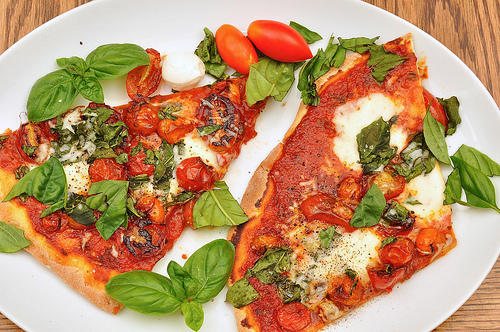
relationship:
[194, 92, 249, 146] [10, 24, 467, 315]
onion on pizza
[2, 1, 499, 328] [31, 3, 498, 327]
plate on table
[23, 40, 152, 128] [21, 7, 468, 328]
basil on plate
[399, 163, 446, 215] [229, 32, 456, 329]
cheese on pizza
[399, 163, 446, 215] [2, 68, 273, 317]
cheese on pizza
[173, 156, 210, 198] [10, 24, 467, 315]
tomato on a pizza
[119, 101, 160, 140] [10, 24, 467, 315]
tomato on a pizza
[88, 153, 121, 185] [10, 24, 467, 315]
tomato on a pizza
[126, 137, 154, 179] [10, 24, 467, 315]
tomatoes on a pizza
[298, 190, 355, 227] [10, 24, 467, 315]
tomatoes on a pizza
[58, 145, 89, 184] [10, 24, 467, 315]
cheese on pizza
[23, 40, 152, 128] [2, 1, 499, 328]
basil on plate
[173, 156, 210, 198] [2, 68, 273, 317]
tomato on a pizza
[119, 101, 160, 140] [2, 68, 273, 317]
tomato on a pizza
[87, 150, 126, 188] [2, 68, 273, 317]
tomato on a pizza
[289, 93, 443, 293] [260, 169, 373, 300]
cheese with spices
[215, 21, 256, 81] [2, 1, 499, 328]
red tomato on plate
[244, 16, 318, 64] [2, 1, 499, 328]
tomatoes on plate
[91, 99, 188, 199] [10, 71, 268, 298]
tomatoes on pizza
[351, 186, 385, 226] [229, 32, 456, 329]
basil on pizza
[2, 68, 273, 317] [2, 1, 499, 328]
pizza on plate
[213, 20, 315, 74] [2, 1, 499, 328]
red tomatoes on plate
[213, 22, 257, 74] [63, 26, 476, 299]
red tomatoes on plate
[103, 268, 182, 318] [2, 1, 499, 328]
leaf on plate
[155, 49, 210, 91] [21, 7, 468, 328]
cheese on plate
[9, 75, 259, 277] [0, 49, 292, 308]
sauce on pizza